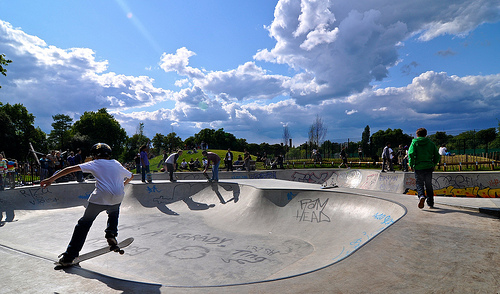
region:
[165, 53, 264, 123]
clouds in the sky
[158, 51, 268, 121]
clouds are white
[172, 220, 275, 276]
writing on the ground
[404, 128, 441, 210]
a person walking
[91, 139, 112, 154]
person wearing a helmet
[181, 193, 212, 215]
a shadow on the ramp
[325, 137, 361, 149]
the green bushes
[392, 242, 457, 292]
the ramp is grey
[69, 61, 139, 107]
the clouds in the sky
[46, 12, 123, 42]
the sky is clear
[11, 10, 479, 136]
Large fluffy clouds in the sky.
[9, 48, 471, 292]
People at a skateboard park.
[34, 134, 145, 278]
Person doing skatrboard trick.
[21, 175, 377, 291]
Graffiti inside the rink.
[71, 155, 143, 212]
A white tee shirt.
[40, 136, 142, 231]
Boy holding arms out for balance.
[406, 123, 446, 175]
Person wearing a green jacket.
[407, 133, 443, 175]
A long sleeve jacket.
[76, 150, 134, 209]
A short sleeve shirt.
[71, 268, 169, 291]
Shadow of skateboarder on ground.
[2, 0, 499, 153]
cloudy blue sky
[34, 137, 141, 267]
person on a skate board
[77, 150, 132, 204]
wrinkly white tee shirt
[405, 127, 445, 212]
person in a green hooded sweat shirt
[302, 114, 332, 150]
tall leafless tree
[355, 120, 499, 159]
grouping of tall leafy green trees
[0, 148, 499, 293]
many people at a skate park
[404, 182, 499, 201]
orange and yellow graffiti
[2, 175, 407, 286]
empty concrete dip for skate boarding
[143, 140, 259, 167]
grassy green hill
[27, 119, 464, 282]
Teenagers skateboarding on a ramp.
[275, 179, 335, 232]
Graffiti on a skateboarding ramp.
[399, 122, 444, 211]
A man wearing a green sweater.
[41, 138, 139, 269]
A boy wearing a white shirt.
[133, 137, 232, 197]
Boys skateboarding at the park.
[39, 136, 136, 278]
A boy wearing a blue and gold helmet.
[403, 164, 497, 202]
Yellow graffiti on a ramp.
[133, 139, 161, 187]
A boy wearing a blue shirt.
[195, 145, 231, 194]
A boy wearing a brown shirt.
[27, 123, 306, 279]
A group of boys skateboarding.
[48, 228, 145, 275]
Boy on a skateboard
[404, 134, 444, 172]
man wearing a green jacket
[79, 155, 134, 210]
boy wearing a white tee shirt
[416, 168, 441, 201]
man wearing blue jeans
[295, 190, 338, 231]
graffiti on the ramp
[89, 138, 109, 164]
man wearing a helmet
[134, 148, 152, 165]
man wearing a purple shirt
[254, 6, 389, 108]
cloudy sky's over the skate park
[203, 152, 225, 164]
person bent over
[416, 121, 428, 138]
man with brown hair